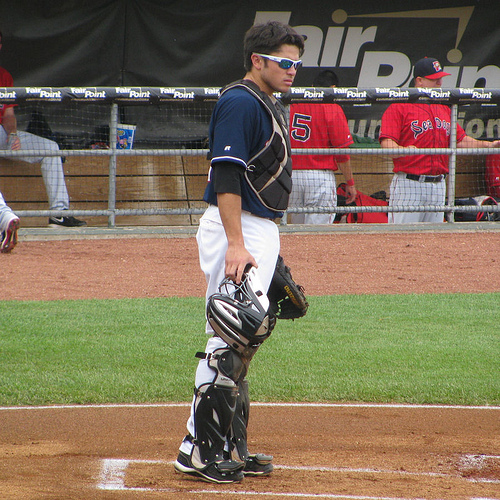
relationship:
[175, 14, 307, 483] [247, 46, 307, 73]
man wearing sunglasses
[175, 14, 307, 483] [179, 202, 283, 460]
man wearing white pants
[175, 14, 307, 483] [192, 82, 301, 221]
man wearing blue shirt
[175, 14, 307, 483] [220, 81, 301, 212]
man wearing black vest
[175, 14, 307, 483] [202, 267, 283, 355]
man holding helmet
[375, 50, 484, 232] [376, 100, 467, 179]
man wearing red baseball shirt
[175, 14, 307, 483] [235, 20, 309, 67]
man with dark brown hair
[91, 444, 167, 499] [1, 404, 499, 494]
white lines in dirt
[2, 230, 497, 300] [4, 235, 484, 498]
red clay on baseball field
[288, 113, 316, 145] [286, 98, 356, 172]
black number 5 on baseball jersey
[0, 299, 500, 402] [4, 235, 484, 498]
green grass on baseball field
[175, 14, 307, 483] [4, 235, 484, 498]
catcher on field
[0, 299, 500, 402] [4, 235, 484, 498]
grass on baseball field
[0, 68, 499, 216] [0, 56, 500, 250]
players in players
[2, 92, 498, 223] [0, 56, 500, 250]
railing of players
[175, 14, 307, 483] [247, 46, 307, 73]
catcher wearing sunglasses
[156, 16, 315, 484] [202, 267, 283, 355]
catcher holding helmet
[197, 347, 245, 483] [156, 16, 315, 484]
knee and shin pads on catcher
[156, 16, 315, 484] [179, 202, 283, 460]
catcher wearing white pants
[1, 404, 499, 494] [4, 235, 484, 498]
dirt on baseball field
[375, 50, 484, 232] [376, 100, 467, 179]
player wearing a red baseball shirt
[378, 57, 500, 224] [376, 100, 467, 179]
man wearing a red baseball shirt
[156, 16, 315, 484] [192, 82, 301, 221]
catcher wearing a blue shirt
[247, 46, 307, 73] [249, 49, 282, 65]
sunglasses have a silver frame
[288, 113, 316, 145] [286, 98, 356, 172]
number on back of red jersey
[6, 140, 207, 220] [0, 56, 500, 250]
wooden bench in players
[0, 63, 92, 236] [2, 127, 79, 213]
baseball player wearing gray pants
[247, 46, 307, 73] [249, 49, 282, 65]
sunglasses with silver frame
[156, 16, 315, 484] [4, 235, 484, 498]
catcher standing on baseball field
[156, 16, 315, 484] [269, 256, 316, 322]
catcher holding leather mitt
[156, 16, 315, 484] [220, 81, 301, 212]
catcher wearing a black vest